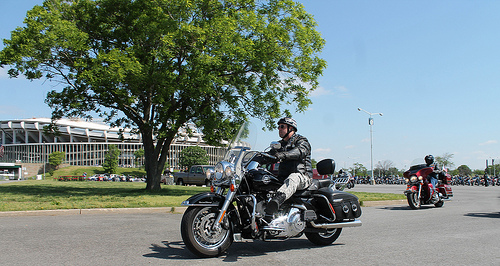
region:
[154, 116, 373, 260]
a man on a motorcycle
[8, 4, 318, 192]
a big leafy tree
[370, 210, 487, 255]
a black top road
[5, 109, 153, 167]
a white large building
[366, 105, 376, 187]
a light on a light pole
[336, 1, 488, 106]
a clear blue sky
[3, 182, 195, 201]
a shadow under a tree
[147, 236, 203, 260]
a shadow of a cycle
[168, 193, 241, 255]
a front wheel on a motor cycle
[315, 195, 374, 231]
side saddles on a cycle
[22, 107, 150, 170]
stadium behind the tree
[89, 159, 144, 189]
vehicles in the parking lot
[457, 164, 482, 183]
motorcycles in the parking lot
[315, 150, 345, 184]
back rest on the motorcycle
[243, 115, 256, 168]
windshield on the motorcycle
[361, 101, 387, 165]
lights in the parking lot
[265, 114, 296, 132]
man wearing a helmet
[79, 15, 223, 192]
tree next to the motorcycle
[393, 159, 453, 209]
motorcycle is red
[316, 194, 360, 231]
motorcycle has luggage bag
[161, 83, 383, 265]
a man riding a motorcycle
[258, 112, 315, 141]
a man wearing a helmet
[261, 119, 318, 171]
a man wearing a black leather jacket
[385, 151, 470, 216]
a red and black motorcycle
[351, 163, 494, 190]
several motorcycles parked together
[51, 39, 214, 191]
a tall green tree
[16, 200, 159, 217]
a concrete curb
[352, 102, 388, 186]
a tall street light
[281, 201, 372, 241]
a chrome muffler on a motorcycle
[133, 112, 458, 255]
two people on motorcycles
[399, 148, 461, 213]
This is a motorbike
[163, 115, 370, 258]
This is a motorbike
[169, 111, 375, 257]
This is a bike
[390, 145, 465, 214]
This is a bike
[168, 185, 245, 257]
Front wheel of a bike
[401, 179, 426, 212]
Front wheel of a bike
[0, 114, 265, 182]
This is a stadium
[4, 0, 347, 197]
This is a tree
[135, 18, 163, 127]
This is a branch of a tree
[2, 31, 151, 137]
This is a branch of a tree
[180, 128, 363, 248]
person on motorcycle in road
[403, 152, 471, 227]
person on motorcycle in road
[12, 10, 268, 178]
large green tree in grass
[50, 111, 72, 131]
leaves on the tree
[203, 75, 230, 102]
leaves on the tree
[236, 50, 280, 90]
leaves on the tree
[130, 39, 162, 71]
leaves on the tree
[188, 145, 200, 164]
leaves on the tree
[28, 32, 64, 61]
leaves on the tree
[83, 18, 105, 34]
leaves on the tree